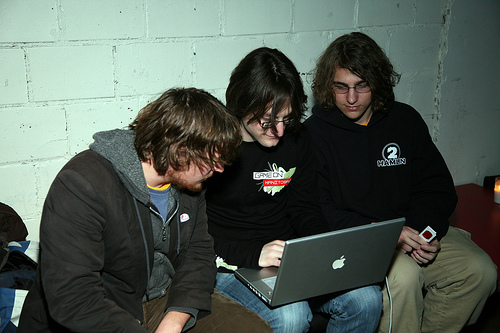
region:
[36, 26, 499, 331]
three young men that need haircuts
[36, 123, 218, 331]
the young man is wearing a grey hoody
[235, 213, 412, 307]
the computer is grey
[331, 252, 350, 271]
an apple logo on the laptop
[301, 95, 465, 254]
boy is wearing black hoody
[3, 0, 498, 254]
the wall is made of cinder blocks painted white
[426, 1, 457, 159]
there is a crack in the wall behind the boy wearing a black hoody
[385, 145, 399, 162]
the black hoody has a number 2 on it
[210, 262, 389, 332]
the young man in the middle is wearing blue jeans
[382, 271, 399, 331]
the laptop has a white power cord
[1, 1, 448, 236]
Cinder block wall behind the people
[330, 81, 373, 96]
Glasses worn by person on the right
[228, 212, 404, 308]
Laptop computer the men are looking at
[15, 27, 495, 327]
Three men looking at the laptop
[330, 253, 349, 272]
Company logo on the back of the computer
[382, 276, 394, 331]
Charger cable for the laptop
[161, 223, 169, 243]
Zipper to the sweatshirt of the man on the left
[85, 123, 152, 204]
Hood of the sweatshirt of the man on the left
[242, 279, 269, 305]
Ports on the side of the computer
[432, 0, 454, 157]
Where the cinder become no longer visible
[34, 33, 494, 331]
THREE MEN LOOKING AT A LABTOP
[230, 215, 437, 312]
AN APPLE LAPTOP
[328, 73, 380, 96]
A PAIR OF GLASSES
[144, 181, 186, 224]
A BLUE TEE SHIRT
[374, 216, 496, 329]
A PAIR OF TAN PANTS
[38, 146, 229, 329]
A BROWN JACKET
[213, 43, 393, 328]
A MAN WEARING BLUE JEANS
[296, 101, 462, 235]
A BLACK SWEAT SHIRT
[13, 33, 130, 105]
A CONCRETE BLOCK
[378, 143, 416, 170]
A WHITE NUMBER 2 ON A BLACK SWEAT SHIRT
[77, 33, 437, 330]
three boys looking at the laptop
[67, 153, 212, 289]
the jacket is gray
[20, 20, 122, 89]
the wall is white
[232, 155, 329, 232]
the shirt is black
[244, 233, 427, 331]
the laptop is silver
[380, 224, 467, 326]
the pants is khaki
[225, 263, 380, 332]
the pants is jeans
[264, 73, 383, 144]
men are wearing eye glasses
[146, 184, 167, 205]
the shirt is blue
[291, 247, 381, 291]
the laptops is apple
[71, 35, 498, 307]
Three man sitting by one another.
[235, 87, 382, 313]
A man is holding a laptop on his legs.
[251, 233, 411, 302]
The laptop is gray.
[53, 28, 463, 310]
Three man are looking at the laptop.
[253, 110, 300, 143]
One man is wearing eyeglasses.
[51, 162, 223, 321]
The jacket is dark gray.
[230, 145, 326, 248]
The shirt is black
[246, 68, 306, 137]
The hair is on the man face.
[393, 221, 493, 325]
The man is wearing beige pants.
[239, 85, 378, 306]
The guy is typing on the laptop.